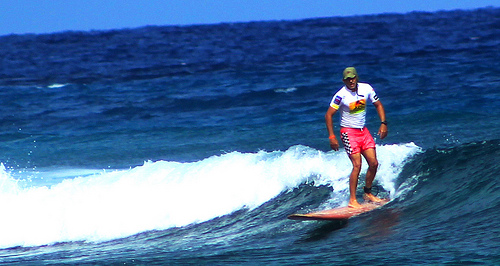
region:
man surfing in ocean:
[277, 63, 428, 240]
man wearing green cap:
[324, 58, 374, 105]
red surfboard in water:
[296, 193, 411, 235]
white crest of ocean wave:
[39, 145, 261, 225]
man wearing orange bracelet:
[313, 96, 350, 175]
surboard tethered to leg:
[347, 164, 418, 242]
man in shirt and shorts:
[292, 58, 430, 188]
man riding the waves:
[266, 68, 403, 243]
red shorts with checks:
[300, 103, 416, 196]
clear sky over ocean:
[64, 6, 194, 67]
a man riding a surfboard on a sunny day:
[325, 62, 387, 206]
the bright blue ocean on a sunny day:
[6, 12, 496, 264]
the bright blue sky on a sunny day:
[1, 0, 496, 29]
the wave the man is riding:
[6, 135, 494, 255]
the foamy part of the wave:
[10, 160, 279, 236]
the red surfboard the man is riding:
[291, 195, 373, 227]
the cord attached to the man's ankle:
[361, 183, 379, 197]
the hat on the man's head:
[341, 66, 354, 79]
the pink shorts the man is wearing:
[334, 120, 375, 155]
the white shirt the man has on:
[328, 77, 383, 132]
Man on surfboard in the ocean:
[294, 65, 393, 222]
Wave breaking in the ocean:
[1, 140, 288, 244]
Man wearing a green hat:
[339, 65, 364, 97]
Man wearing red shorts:
[336, 116, 381, 153]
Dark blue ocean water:
[6, 31, 288, 140]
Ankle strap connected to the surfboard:
[359, 176, 382, 206]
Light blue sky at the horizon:
[2, 0, 498, 30]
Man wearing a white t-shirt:
[328, 83, 379, 128]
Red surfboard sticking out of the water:
[284, 200, 386, 225]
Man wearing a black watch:
[339, 66, 387, 133]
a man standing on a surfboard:
[318, 65, 391, 213]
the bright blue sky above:
[3, 0, 490, 27]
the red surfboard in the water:
[289, 203, 381, 225]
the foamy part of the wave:
[1, 142, 426, 246]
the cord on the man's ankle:
[360, 180, 380, 197]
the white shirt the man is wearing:
[328, 81, 380, 131]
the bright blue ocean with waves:
[9, 12, 499, 263]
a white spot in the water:
[44, 80, 68, 90]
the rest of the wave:
[248, 136, 498, 259]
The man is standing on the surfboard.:
[325, 55, 395, 232]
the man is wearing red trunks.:
[330, 130, 378, 151]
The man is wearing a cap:
[329, 62, 374, 83]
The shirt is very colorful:
[333, 99, 385, 124]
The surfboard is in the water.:
[290, 201, 387, 233]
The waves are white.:
[90, 156, 322, 206]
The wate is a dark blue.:
[83, 41, 316, 123]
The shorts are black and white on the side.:
[331, 128, 354, 160]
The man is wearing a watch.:
[374, 118, 406, 134]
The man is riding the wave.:
[301, 86, 389, 219]